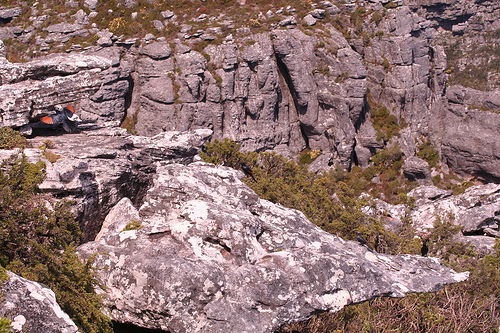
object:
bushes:
[212, 109, 451, 261]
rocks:
[6, 6, 496, 331]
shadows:
[420, 2, 450, 13]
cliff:
[85, 3, 492, 105]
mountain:
[1, 0, 500, 333]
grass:
[3, 187, 110, 318]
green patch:
[447, 46, 498, 85]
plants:
[141, 112, 493, 330]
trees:
[6, 164, 80, 287]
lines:
[139, 91, 265, 107]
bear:
[15, 107, 84, 139]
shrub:
[4, 33, 103, 64]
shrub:
[231, 3, 291, 30]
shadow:
[273, 50, 303, 119]